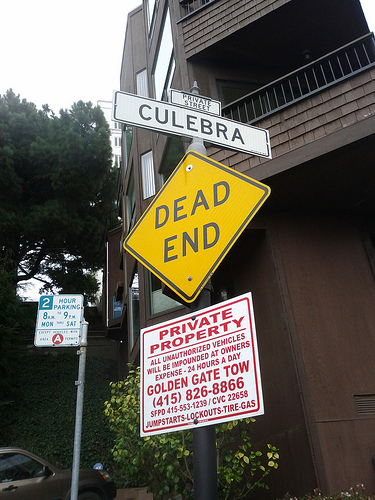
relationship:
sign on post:
[18, 282, 75, 351] [60, 363, 98, 436]